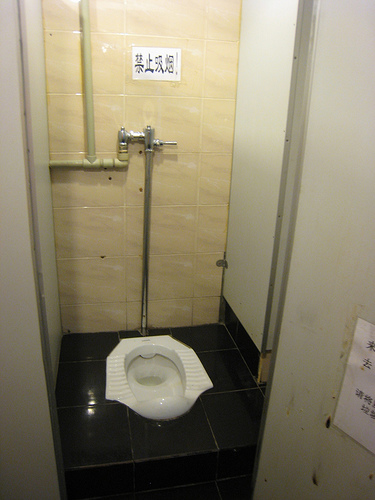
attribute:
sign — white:
[130, 45, 180, 83]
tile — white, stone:
[200, 35, 241, 101]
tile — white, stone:
[196, 93, 238, 155]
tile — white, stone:
[193, 146, 235, 209]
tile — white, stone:
[190, 200, 231, 254]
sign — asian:
[127, 40, 183, 84]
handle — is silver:
[158, 138, 179, 147]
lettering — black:
[138, 52, 207, 79]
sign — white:
[112, 40, 196, 97]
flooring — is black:
[57, 314, 265, 473]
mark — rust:
[280, 386, 298, 423]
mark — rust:
[321, 409, 331, 435]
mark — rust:
[309, 468, 319, 488]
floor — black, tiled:
[66, 329, 256, 497]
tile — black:
[62, 401, 138, 466]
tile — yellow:
[80, 259, 125, 302]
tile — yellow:
[155, 206, 197, 253]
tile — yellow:
[199, 155, 227, 205]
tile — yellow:
[78, 93, 124, 152]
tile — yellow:
[202, 95, 228, 152]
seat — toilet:
[103, 334, 211, 418]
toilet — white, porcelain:
[101, 333, 210, 417]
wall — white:
[222, 5, 363, 380]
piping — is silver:
[134, 169, 157, 329]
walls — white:
[237, 112, 269, 174]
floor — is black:
[55, 318, 270, 498]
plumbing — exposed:
[46, 1, 178, 333]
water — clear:
[129, 363, 176, 392]